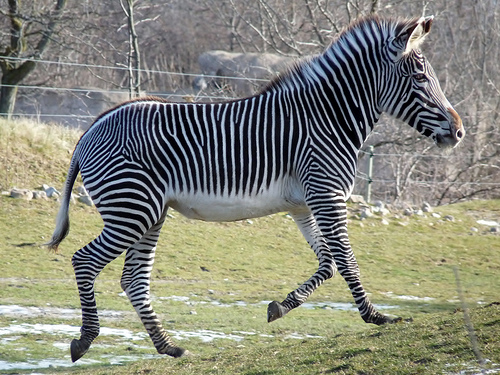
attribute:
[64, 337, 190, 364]
hoofs — zebra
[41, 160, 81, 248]
tail — zebra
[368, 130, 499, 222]
fence — cable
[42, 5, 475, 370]
zebra — fur , stripes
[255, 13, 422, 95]
mane — black, white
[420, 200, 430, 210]
rocks — cluster 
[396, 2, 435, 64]
ears — zebras, erect, striped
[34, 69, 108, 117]
rock — formation 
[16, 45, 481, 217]
fence — barbed, wire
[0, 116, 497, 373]
field — green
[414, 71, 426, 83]
eye — zebra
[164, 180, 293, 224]
belly — white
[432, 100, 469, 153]
muzzle — brown, topped, zebras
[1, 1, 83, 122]
tree — bare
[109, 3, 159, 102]
tree — bare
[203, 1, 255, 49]
tree — bare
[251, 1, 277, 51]
tree — bare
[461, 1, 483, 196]
tree — bare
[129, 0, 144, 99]
tree — leafless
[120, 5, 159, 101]
tree — leafless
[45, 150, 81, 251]
tail — zebra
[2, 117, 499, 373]
grass — green